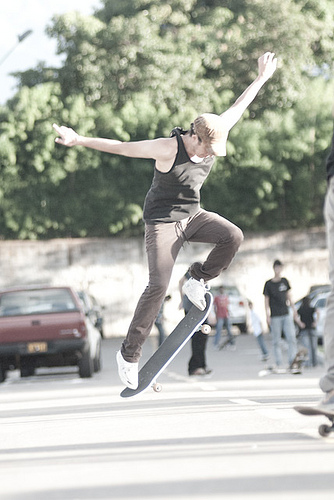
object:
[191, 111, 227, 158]
hat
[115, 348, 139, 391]
shoes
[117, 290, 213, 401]
board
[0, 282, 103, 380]
car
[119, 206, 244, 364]
pants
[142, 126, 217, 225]
shirt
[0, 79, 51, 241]
trees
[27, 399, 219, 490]
road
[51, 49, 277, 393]
boy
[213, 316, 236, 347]
jeans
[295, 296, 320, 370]
woman